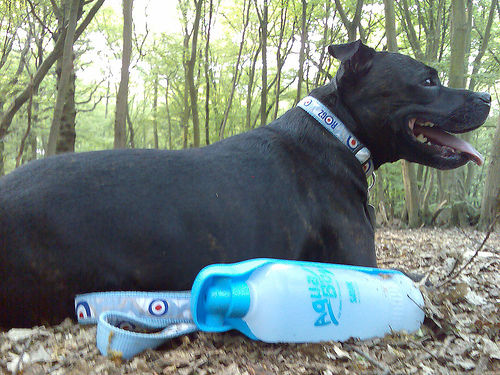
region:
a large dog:
[16, 52, 482, 287]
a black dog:
[28, 53, 499, 304]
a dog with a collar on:
[12, 53, 484, 249]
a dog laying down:
[13, 45, 487, 270]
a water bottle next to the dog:
[211, 246, 426, 341]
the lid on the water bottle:
[201, 287, 227, 313]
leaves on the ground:
[434, 233, 498, 371]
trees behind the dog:
[11, 23, 494, 140]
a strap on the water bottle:
[83, 285, 170, 340]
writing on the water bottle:
[303, 263, 352, 331]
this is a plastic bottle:
[173, 239, 438, 348]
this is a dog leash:
[61, 283, 208, 364]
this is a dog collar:
[280, 93, 391, 173]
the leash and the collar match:
[73, 69, 394, 372]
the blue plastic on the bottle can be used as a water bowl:
[167, 225, 444, 358]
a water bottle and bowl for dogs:
[167, 245, 484, 374]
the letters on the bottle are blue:
[295, 251, 365, 331]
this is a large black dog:
[5, 7, 499, 295]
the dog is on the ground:
[1, 16, 498, 328]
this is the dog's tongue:
[412, 121, 499, 171]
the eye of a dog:
[413, 72, 438, 90]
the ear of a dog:
[320, 38, 372, 76]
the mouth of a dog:
[395, 103, 485, 169]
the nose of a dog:
[478, 90, 494, 104]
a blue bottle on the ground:
[188, 260, 430, 345]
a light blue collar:
[294, 95, 381, 192]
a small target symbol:
[145, 297, 168, 317]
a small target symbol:
[74, 300, 94, 320]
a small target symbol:
[345, 132, 359, 149]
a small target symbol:
[324, 114, 334, 126]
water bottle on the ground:
[191, 253, 428, 337]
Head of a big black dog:
[296, 25, 488, 181]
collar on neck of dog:
[283, 82, 383, 179]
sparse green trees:
[136, 20, 269, 107]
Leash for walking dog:
[73, 290, 187, 350]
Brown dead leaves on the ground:
[446, 246, 495, 354]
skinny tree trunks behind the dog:
[25, 37, 96, 137]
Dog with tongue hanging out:
[408, 116, 499, 163]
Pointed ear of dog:
[325, 35, 370, 75]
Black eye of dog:
[410, 60, 441, 95]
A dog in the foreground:
[0, 32, 492, 334]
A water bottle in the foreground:
[173, 242, 444, 355]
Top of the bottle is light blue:
[188, 266, 256, 337]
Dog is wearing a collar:
[289, 89, 392, 186]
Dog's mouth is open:
[402, 102, 493, 179]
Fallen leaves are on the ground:
[1, 222, 498, 374]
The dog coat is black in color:
[3, 30, 496, 338]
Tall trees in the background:
[1, 2, 498, 230]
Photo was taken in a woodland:
[1, 2, 494, 374]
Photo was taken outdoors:
[5, 2, 495, 374]